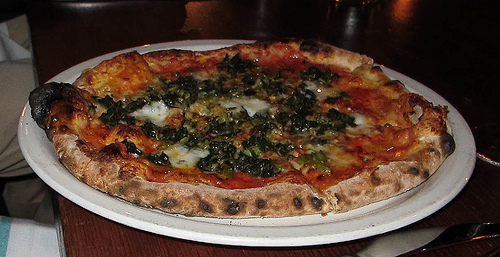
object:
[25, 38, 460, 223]
pizza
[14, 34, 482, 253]
dish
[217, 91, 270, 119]
cheese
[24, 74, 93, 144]
crust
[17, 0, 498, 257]
table